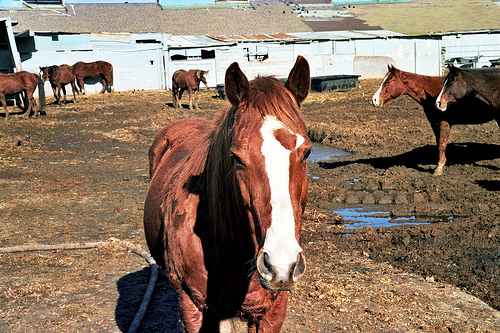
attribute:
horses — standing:
[0, 60, 499, 331]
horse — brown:
[143, 55, 315, 331]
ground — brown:
[0, 78, 499, 332]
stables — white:
[0, 0, 498, 99]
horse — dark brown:
[436, 62, 500, 122]